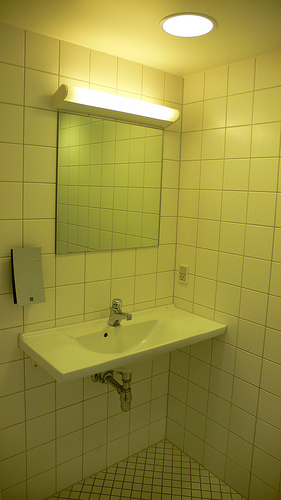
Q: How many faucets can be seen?
A: One.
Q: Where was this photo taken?
A: A bathroom.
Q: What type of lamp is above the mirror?
A: Fluorescent.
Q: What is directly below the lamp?
A: A mirror.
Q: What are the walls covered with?
A: Tiles.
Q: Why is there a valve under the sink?
A: To control water flow.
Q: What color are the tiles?
A: White.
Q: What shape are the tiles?
A: Square.